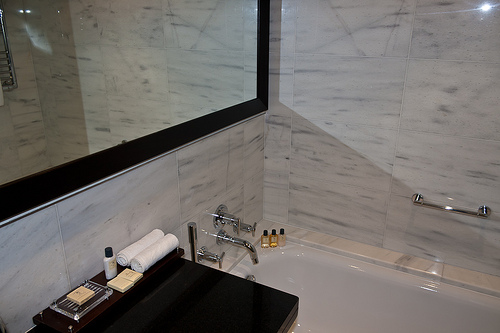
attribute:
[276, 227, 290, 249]
bottle — small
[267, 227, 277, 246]
bottle — small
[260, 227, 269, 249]
bottle — small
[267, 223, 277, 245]
bottle — small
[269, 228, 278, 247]
bottle — small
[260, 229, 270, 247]
bottle — small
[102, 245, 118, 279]
bottle — small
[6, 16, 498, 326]
bathroom — beautiful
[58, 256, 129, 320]
box — small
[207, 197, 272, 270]
fixtures — chrome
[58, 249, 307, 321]
counter — black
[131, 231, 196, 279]
hand towel — rolled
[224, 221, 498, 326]
bath tub — white, ceramic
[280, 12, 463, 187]
tiles — marble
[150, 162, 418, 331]
bath tub — large, white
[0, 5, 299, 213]
mirror — rectangular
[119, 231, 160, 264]
hand towel — rolled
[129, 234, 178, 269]
hand towel — rolled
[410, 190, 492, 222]
safety bar — chrome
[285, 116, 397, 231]
tile — grey, white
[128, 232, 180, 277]
towels — white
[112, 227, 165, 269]
towels — white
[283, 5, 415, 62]
tile — grey, white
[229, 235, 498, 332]
bathtub — white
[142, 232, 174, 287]
hand towel — white, rolled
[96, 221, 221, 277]
two towels — rolled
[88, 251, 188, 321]
box — small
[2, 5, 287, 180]
mirror — trimmed, black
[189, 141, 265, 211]
tile — white, grey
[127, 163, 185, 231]
tile — grey, white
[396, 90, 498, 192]
tile — white, grey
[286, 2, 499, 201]
walls — marble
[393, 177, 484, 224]
rod — silver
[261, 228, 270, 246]
bottle — small